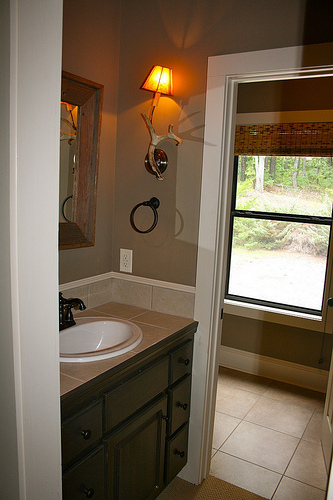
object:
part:
[301, 0, 332, 69]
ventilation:
[297, 3, 333, 76]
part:
[209, 373, 256, 476]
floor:
[156, 373, 333, 498]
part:
[62, 373, 130, 499]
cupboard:
[61, 322, 197, 499]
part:
[61, 319, 130, 359]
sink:
[57, 314, 143, 366]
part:
[133, 217, 157, 233]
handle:
[128, 198, 161, 235]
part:
[120, 260, 132, 271]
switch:
[120, 248, 133, 273]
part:
[156, 479, 207, 500]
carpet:
[149, 471, 265, 499]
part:
[229, 233, 283, 252]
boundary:
[234, 232, 327, 258]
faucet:
[57, 290, 86, 330]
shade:
[141, 65, 174, 98]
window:
[222, 146, 331, 314]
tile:
[217, 419, 301, 477]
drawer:
[167, 339, 194, 390]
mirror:
[58, 73, 97, 245]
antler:
[140, 108, 183, 181]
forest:
[233, 152, 328, 253]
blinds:
[231, 123, 330, 158]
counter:
[57, 300, 198, 399]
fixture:
[135, 92, 182, 176]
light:
[139, 65, 175, 113]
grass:
[254, 259, 269, 283]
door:
[206, 76, 331, 497]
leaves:
[247, 156, 253, 187]